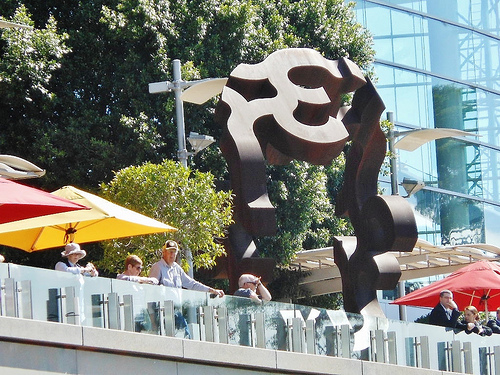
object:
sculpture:
[217, 46, 418, 318]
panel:
[112, 280, 207, 342]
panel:
[16, 267, 119, 332]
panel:
[211, 297, 292, 352]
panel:
[295, 306, 380, 360]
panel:
[376, 316, 454, 368]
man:
[417, 287, 461, 329]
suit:
[431, 302, 466, 333]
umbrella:
[0, 184, 178, 253]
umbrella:
[0, 172, 89, 225]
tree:
[94, 156, 237, 275]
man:
[147, 239, 226, 296]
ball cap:
[161, 237, 181, 253]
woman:
[116, 254, 162, 286]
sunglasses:
[132, 263, 143, 272]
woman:
[53, 239, 97, 280]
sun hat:
[60, 241, 88, 261]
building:
[340, 0, 500, 331]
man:
[232, 273, 274, 305]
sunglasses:
[247, 280, 259, 285]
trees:
[0, 0, 385, 299]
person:
[460, 303, 492, 336]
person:
[485, 309, 500, 333]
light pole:
[172, 57, 192, 167]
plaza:
[0, 11, 498, 362]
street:
[0, 283, 499, 373]